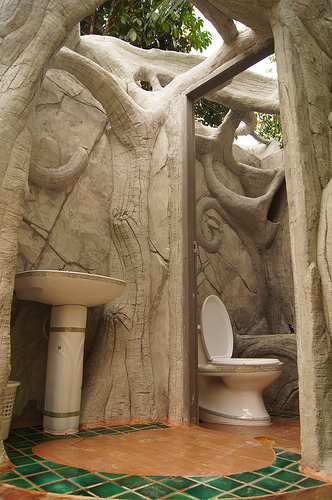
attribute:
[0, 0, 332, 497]
walls — carved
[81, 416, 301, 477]
area — brown, circular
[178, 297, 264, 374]
seat — uplifted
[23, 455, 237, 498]
tiles — green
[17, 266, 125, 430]
sink — white